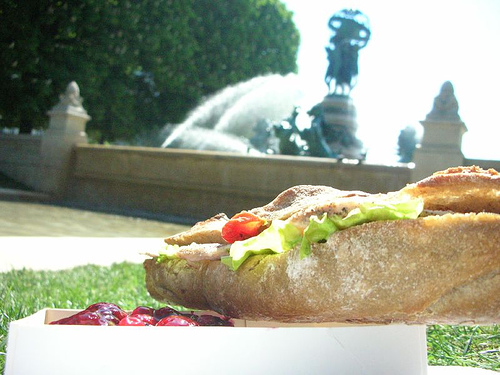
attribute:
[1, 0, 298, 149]
tree — green, large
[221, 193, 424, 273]
lettuce leaf — Green 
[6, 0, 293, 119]
tree — green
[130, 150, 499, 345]
sandwich — crusty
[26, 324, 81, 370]
box — white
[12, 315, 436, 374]
box — white, cardboard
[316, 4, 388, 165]
figures — muted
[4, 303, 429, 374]
food box — white 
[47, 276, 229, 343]
sauce — red, cranberry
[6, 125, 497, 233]
wall — concrete, retaining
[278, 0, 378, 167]
fountain — water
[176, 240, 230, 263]
meat — lunch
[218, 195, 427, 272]
lettuce — green, leaf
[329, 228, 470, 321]
bread — brown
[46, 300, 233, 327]
berries — red 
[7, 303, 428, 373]
box — white, open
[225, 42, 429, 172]
figures — curved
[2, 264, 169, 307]
grass — green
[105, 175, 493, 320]
bread — brown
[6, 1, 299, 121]
leaves — green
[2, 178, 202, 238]
floor — stone